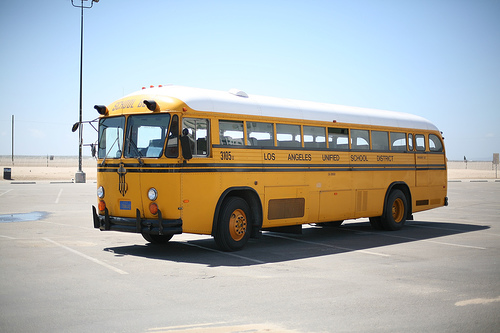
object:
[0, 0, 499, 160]
sky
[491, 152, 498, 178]
street sign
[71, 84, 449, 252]
school bus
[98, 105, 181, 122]
vintage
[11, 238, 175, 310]
parking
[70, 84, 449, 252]
bus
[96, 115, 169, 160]
windshield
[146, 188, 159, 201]
headlight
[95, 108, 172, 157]
front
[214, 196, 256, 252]
big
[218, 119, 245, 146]
window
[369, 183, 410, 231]
wheels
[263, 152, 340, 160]
letters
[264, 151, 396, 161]
words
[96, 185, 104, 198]
right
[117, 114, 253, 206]
left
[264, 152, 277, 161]
los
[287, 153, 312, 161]
angeles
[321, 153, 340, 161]
unified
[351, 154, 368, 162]
school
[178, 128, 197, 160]
mirror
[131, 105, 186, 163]
driver side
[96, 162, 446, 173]
black stripes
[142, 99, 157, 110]
light fixtures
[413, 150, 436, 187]
emergency exit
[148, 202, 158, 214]
reflectors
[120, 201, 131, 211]
license plate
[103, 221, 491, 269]
shadow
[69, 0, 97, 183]
light post